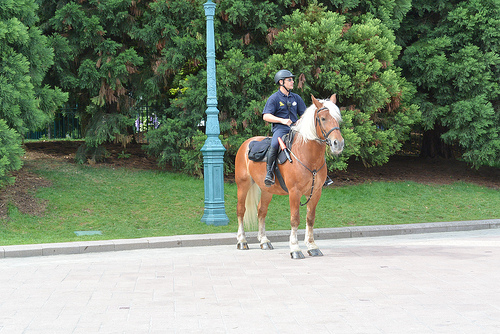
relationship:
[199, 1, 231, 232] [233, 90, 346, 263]
pole behind horse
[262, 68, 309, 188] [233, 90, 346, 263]
officer on top of horse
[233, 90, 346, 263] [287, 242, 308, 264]
horse has front foot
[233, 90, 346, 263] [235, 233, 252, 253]
horse has back foot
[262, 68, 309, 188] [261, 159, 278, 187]
officer wears boot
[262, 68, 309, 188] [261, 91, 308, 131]
officer wears suit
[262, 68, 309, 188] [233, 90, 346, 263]
officer patrolling on horse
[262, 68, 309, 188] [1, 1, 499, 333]
officer patrolling park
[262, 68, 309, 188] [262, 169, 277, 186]
officer has foot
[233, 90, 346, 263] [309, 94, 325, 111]
horse has ear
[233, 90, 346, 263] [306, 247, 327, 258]
horse has hoof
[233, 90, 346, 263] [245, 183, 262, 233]
horse has tail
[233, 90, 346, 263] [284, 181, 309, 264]
horse has leg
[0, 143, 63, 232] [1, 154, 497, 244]
dirt in between grass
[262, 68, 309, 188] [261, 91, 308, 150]
officer wearing suit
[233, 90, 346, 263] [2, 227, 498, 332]
horse standing in street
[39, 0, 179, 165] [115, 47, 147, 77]
tree has leaves